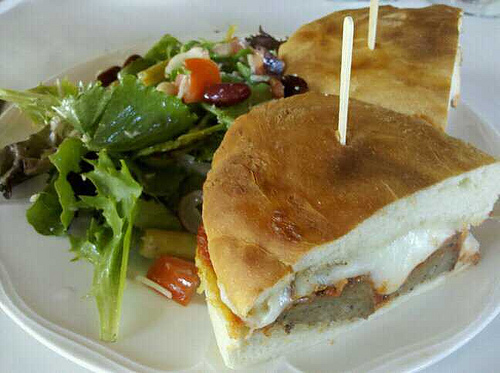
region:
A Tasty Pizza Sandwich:
[211, 116, 473, 355]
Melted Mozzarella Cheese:
[323, 223, 468, 294]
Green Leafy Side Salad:
[43, 19, 175, 287]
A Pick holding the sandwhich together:
[323, 7, 364, 169]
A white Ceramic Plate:
[2, 254, 84, 361]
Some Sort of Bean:
[197, 66, 259, 114]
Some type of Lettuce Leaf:
[79, 85, 189, 158]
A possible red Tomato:
[170, 56, 224, 103]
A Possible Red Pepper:
[143, 253, 198, 305]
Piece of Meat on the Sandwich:
[286, 295, 364, 323]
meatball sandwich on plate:
[199, 87, 497, 353]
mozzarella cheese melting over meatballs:
[214, 212, 476, 322]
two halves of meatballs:
[270, 229, 464, 344]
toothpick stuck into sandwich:
[334, 9, 356, 148]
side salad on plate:
[8, 28, 306, 315]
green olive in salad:
[179, 182, 214, 234]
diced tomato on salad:
[146, 254, 203, 304]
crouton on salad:
[137, 228, 197, 264]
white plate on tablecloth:
[2, 27, 497, 371]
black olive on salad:
[202, 69, 247, 106]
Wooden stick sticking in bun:
[342, 11, 346, 137]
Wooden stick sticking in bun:
[359, 6, 381, 55]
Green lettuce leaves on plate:
[51, 96, 253, 320]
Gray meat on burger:
[280, 268, 480, 330]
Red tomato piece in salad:
[178, 40, 234, 115]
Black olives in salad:
[275, 73, 310, 95]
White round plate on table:
[29, 82, 485, 342]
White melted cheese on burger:
[309, 205, 481, 306]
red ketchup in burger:
[313, 270, 393, 309]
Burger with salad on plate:
[48, 19, 495, 249]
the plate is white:
[24, 39, 492, 364]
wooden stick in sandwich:
[316, 8, 366, 167]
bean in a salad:
[199, 73, 253, 113]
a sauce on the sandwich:
[284, 207, 467, 318]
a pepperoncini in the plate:
[130, 226, 200, 261]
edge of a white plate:
[4, 286, 127, 367]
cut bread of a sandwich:
[226, 128, 498, 367]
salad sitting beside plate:
[12, 26, 289, 307]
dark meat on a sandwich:
[249, 221, 469, 351]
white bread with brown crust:
[233, 136, 496, 331]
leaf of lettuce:
[78, 148, 146, 341]